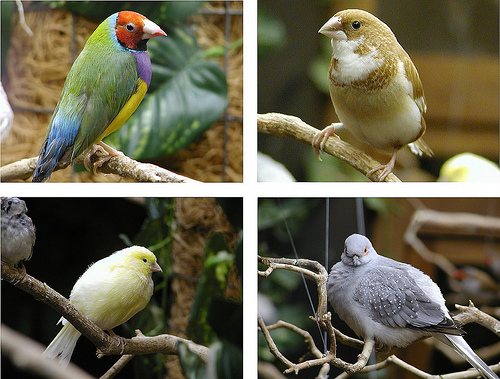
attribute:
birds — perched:
[34, 6, 499, 377]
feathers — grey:
[323, 230, 496, 374]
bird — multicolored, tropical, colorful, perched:
[20, 12, 173, 179]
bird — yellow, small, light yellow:
[40, 244, 167, 369]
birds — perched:
[23, 7, 441, 179]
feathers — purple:
[131, 50, 159, 88]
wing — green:
[70, 45, 137, 162]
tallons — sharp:
[306, 126, 399, 183]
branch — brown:
[2, 144, 217, 182]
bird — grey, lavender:
[325, 233, 472, 368]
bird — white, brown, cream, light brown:
[309, 9, 435, 175]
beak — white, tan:
[318, 16, 352, 46]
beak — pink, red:
[146, 25, 172, 39]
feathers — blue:
[45, 120, 82, 149]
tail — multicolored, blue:
[32, 139, 75, 178]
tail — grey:
[443, 321, 495, 378]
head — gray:
[339, 232, 374, 267]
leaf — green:
[129, 33, 232, 166]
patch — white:
[325, 35, 375, 79]